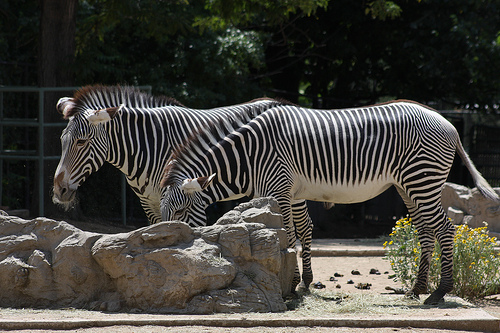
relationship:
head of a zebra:
[48, 73, 107, 207] [45, 82, 321, 292]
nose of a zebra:
[50, 178, 71, 201] [45, 82, 321, 292]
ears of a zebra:
[53, 83, 123, 124] [45, 82, 321, 292]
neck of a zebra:
[117, 85, 164, 179] [45, 82, 321, 292]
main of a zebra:
[75, 78, 185, 116] [45, 82, 321, 292]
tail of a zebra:
[451, 146, 482, 188] [156, 99, 500, 304]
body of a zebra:
[282, 115, 418, 177] [156, 99, 500, 304]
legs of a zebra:
[393, 188, 458, 303] [156, 99, 500, 304]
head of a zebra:
[50, 95, 125, 204] [45, 82, 321, 292]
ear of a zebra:
[80, 101, 123, 126] [36, 73, 296, 268]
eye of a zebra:
[70, 131, 92, 151] [46, 70, 278, 289]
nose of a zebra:
[50, 175, 70, 204] [46, 70, 278, 289]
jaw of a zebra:
[54, 160, 92, 200] [47, 70, 287, 273]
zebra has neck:
[45, 82, 321, 292] [110, 103, 166, 193]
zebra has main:
[45, 82, 321, 292] [71, 81, 174, 109]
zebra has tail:
[156, 99, 500, 304] [457, 128, 498, 215]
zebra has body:
[45, 82, 321, 292] [156, 118, 288, 184]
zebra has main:
[45, 82, 321, 292] [68, 75, 190, 115]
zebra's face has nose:
[47, 78, 321, 304] [49, 167, 69, 188]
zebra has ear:
[156, 99, 500, 304] [179, 174, 213, 195]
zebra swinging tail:
[156, 99, 500, 304] [456, 135, 498, 204]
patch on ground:
[333, 290, 414, 317] [289, 274, 436, 322]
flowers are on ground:
[388, 215, 492, 296] [327, 262, 496, 327]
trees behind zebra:
[68, 7, 487, 95] [45, 82, 321, 292]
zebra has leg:
[156, 99, 500, 304] [409, 188, 467, 308]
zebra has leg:
[156, 99, 494, 300] [403, 179, 463, 301]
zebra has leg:
[156, 99, 500, 304] [291, 199, 321, 294]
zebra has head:
[156, 99, 500, 304] [154, 142, 239, 227]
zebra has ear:
[156, 99, 500, 304] [180, 174, 206, 195]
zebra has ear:
[45, 82, 321, 292] [53, 94, 80, 118]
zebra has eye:
[45, 82, 321, 292] [73, 133, 88, 150]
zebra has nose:
[45, 82, 321, 292] [52, 164, 72, 185]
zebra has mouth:
[45, 82, 321, 292] [52, 183, 78, 201]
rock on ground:
[20, 249, 56, 299] [5, 290, 291, 332]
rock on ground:
[20, 249, 56, 299] [1, 250, 481, 330]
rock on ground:
[83, 296, 101, 312] [1, 250, 481, 330]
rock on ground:
[20, 249, 56, 299] [14, 218, 484, 328]